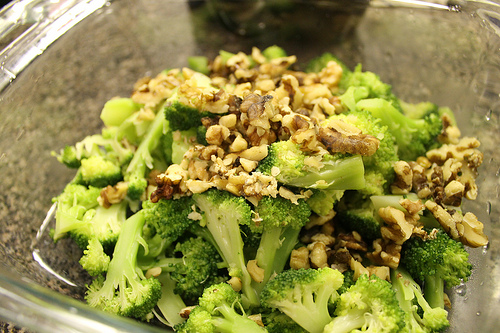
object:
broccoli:
[260, 267, 345, 332]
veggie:
[356, 98, 441, 159]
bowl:
[0, 0, 500, 332]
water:
[450, 282, 470, 295]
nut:
[238, 142, 270, 163]